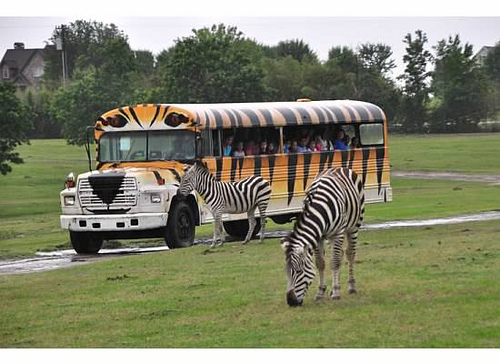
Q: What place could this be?
A: It is a field.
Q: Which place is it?
A: It is a field.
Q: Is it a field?
A: Yes, it is a field.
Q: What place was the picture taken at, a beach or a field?
A: It was taken at a field.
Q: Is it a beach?
A: No, it is a field.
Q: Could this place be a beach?
A: No, it is a field.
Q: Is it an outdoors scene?
A: Yes, it is outdoors.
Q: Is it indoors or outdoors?
A: It is outdoors.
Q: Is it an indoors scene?
A: No, it is outdoors.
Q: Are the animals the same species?
A: Yes, all the animals are zebras.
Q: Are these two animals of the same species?
A: Yes, all the animals are zebras.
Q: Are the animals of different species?
A: No, all the animals are zebras.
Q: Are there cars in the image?
A: No, there are no cars.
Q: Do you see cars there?
A: No, there are no cars.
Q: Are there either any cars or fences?
A: No, there are no cars or fences.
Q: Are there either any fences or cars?
A: No, there are no cars or fences.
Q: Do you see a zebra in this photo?
A: Yes, there is a zebra.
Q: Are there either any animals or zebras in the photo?
A: Yes, there is a zebra.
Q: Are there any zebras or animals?
A: Yes, there is a zebra.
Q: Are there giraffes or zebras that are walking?
A: Yes, the zebra is walking.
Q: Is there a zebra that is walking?
A: Yes, there is a zebra that is walking.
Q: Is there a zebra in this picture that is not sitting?
A: Yes, there is a zebra that is walking.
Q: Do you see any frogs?
A: No, there are no frogs.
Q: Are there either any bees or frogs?
A: No, there are no frogs or bees.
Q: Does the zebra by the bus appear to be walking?
A: Yes, the zebra is walking.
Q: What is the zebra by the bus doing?
A: The zebra is walking.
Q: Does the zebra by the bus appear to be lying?
A: No, the zebra is walking.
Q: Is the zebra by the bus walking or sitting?
A: The zebra is walking.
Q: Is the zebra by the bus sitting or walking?
A: The zebra is walking.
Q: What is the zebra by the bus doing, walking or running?
A: The zebra is walking.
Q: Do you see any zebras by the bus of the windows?
A: Yes, there is a zebra by the bus.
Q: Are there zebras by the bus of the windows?
A: Yes, there is a zebra by the bus.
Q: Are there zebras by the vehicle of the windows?
A: Yes, there is a zebra by the bus.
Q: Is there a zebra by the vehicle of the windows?
A: Yes, there is a zebra by the bus.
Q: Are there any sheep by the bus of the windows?
A: No, there is a zebra by the bus.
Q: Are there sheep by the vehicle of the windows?
A: No, there is a zebra by the bus.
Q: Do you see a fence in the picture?
A: No, there are no fences.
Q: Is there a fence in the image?
A: No, there are no fences.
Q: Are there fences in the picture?
A: No, there are no fences.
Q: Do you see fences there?
A: No, there are no fences.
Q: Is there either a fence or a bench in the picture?
A: No, there are no fences or benches.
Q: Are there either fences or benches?
A: No, there are no fences or benches.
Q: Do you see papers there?
A: No, there are no papers.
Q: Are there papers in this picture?
A: No, there are no papers.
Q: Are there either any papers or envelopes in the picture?
A: No, there are no papers or envelopes.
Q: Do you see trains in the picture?
A: No, there are no trains.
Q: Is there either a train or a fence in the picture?
A: No, there are no trains or fences.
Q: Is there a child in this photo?
A: Yes, there are children.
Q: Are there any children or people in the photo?
A: Yes, there are children.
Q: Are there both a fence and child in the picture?
A: No, there are children but no fences.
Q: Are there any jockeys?
A: No, there are no jockeys.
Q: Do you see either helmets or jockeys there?
A: No, there are no jockeys or helmets.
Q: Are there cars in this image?
A: No, there are no cars.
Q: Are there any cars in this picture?
A: No, there are no cars.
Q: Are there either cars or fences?
A: No, there are no cars or fences.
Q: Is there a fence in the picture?
A: No, there are no fences.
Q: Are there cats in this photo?
A: No, there are no cats.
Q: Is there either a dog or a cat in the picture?
A: No, there are no cats or dogs.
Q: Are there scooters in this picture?
A: No, there are no scooters.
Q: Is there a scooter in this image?
A: No, there are no scooters.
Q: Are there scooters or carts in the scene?
A: No, there are no scooters or carts.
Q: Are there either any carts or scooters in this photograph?
A: No, there are no scooters or carts.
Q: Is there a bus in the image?
A: Yes, there is a bus.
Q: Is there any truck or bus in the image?
A: Yes, there is a bus.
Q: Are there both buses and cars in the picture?
A: No, there is a bus but no cars.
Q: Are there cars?
A: No, there are no cars.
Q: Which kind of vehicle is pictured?
A: The vehicle is a bus.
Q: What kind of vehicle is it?
A: The vehicle is a bus.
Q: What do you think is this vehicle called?
A: This is a bus.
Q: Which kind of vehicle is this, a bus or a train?
A: This is a bus.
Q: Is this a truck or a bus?
A: This is a bus.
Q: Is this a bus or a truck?
A: This is a bus.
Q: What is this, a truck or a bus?
A: This is a bus.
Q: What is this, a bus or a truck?
A: This is a bus.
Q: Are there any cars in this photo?
A: No, there are no cars.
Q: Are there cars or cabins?
A: No, there are no cars or cabins.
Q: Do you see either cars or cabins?
A: No, there are no cars or cabins.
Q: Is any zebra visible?
A: Yes, there is a zebra.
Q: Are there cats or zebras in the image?
A: Yes, there is a zebra.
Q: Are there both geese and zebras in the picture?
A: No, there is a zebra but no geese.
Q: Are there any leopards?
A: No, there are no leopards.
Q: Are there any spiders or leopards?
A: No, there are no leopards or spiders.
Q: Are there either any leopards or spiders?
A: No, there are no leopards or spiders.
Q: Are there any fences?
A: No, there are no fences.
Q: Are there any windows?
A: Yes, there are windows.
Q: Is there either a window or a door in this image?
A: Yes, there are windows.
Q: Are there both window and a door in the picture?
A: No, there are windows but no doors.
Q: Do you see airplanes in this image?
A: No, there are no airplanes.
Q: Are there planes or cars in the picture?
A: No, there are no planes or cars.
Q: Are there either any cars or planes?
A: No, there are no planes or cars.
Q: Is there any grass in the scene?
A: Yes, there is grass.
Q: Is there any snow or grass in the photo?
A: Yes, there is grass.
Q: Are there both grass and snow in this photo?
A: No, there is grass but no snow.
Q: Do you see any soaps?
A: No, there are no soaps.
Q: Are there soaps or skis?
A: No, there are no soaps or skis.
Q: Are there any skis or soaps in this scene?
A: No, there are no soaps or skis.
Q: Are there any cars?
A: No, there are no cars.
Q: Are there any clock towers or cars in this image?
A: No, there are no cars or clock towers.